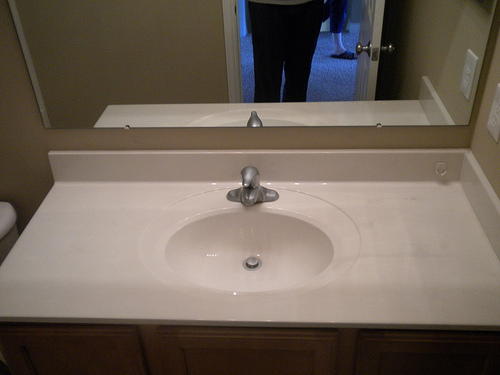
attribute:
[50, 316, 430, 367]
doors — wooden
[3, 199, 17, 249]
toilet tank — white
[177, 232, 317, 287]
metal sink — Metal 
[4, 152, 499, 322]
sink top — white, porcelain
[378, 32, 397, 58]
knob — metal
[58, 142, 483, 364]
bathroom — brown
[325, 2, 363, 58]
person — standing up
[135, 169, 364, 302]
sink drain — silver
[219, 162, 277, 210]
faucet — silver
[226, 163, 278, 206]
faucet — silver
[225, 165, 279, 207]
metal/sink part — Metal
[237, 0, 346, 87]
person — standing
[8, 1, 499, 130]
mirror — reflective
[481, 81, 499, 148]
wall plug — white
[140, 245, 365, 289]
sink — porcelain, white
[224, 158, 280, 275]
metal part — sink